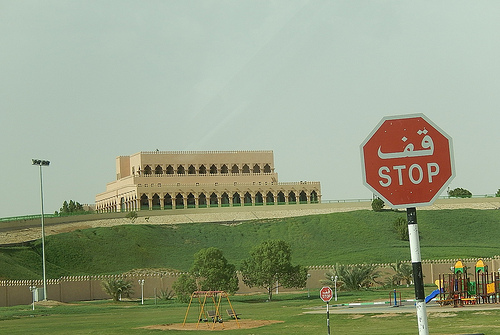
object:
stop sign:
[360, 112, 457, 209]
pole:
[406, 207, 429, 335]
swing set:
[181, 288, 241, 331]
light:
[32, 159, 50, 166]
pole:
[40, 165, 48, 301]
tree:
[240, 239, 309, 302]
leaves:
[264, 248, 282, 259]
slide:
[415, 289, 440, 306]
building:
[94, 148, 322, 214]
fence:
[0, 255, 499, 307]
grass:
[27, 307, 140, 333]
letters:
[378, 163, 440, 188]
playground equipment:
[415, 260, 500, 308]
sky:
[1, 2, 500, 91]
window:
[166, 165, 174, 174]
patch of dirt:
[131, 318, 283, 330]